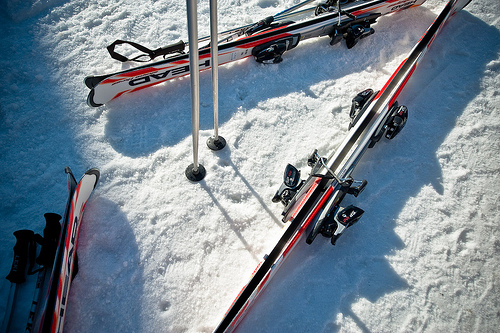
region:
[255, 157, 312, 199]
black ski brackets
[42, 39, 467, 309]
three pairs of skis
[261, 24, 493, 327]
shadow of skis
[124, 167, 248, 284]
sun light on snow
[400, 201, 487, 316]
hard packed snow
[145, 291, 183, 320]
ski pole marks in snow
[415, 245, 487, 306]
foot prints in snow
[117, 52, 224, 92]
HEAD label on ski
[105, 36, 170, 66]
black wrist band for ski pole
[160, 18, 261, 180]
silver colored ski poles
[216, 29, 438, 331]
Red and white skis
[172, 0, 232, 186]
Two poles for skiing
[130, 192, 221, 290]
White powdery, glaring snow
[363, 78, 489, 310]
Shadow of two skis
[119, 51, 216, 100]
Brand of the skis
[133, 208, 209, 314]
Foot prints in the snow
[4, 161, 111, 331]
Two skis and two poles for skiing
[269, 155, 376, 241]
Where you put your feet for skiing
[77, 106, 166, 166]
A shoe print in the snow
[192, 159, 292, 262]
Shadow of the poles for skiing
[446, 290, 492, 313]
This is ice in the picture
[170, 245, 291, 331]
This is a red skating board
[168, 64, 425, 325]
These are playing tools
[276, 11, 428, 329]
This is skating gear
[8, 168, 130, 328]
This is a red skating board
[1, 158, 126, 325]
This is red and white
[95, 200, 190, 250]
This is white ice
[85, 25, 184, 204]
This is a tail of a board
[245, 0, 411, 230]
These are the wheels of a skating board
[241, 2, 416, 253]
These are the wheels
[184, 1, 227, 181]
a pair of ski poles are stuck into the ground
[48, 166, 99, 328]
a pair of red, black and white skis laying on the ground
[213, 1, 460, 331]
another pair of red, black and white skis laying on the ground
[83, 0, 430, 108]
third pair of red, black and white skis on the ground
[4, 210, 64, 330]
a pair of ski poles lie next to a pair of skis.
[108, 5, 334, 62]
Another pair of ski poles lie next to the skis.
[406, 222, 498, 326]
footprints surround the skis and poles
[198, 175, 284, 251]
shadow cast by the standing ski poles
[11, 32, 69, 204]
shadow on the left side of the photo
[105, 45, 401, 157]
shadow cast by the skis lying on their side.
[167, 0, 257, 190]
Two ski poles stuck in the snow.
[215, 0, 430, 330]
The skis are red, white, and black.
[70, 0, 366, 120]
Two ski poles next to a pair of skis.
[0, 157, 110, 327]
A pair of ski poles laying next to a pair of skis.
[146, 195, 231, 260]
Sun is shining on the snow.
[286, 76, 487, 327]
A shadow next to the pair of skis.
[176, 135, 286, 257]
The shadow of the ski poles.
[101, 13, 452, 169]
The shadow of the skis.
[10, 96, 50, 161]
A shadow on the snow.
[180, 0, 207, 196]
The ski pole is skinny.